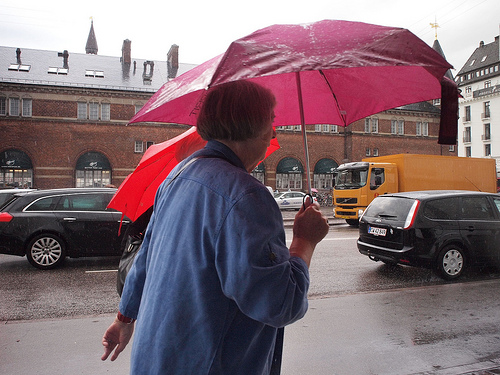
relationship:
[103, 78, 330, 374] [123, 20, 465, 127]
person has umbrella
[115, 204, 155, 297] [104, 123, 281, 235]
person has umbrella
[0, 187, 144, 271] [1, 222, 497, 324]
car on road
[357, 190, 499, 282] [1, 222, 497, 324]
car on road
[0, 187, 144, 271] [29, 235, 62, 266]
car has rims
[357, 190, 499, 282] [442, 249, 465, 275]
car has rims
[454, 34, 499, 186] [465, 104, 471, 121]
building has window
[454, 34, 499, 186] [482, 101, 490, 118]
building has window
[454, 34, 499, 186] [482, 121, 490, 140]
building has window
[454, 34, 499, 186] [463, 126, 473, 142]
building has window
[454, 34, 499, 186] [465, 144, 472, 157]
building has window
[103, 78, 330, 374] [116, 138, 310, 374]
person wearing shirt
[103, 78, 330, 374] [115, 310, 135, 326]
person wearing watch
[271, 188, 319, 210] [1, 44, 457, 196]
car near building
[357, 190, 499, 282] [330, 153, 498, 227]
car near truck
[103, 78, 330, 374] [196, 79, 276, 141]
person has hair